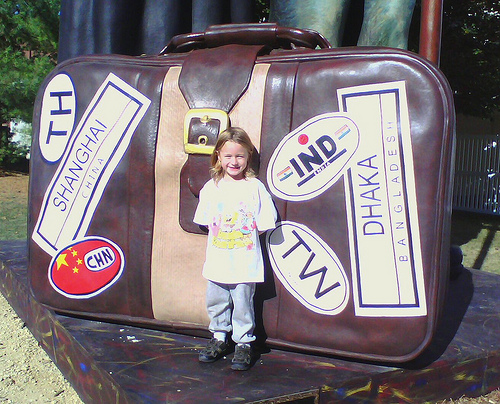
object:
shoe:
[231, 344, 255, 372]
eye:
[224, 155, 232, 158]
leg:
[231, 281, 257, 344]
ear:
[215, 150, 222, 161]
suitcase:
[21, 18, 461, 370]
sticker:
[265, 109, 368, 202]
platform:
[0, 241, 500, 404]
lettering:
[315, 134, 337, 160]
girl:
[189, 126, 276, 366]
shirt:
[192, 175, 279, 287]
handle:
[156, 21, 332, 54]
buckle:
[182, 108, 231, 156]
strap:
[290, 28, 333, 50]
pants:
[204, 280, 259, 346]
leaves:
[12, 23, 34, 40]